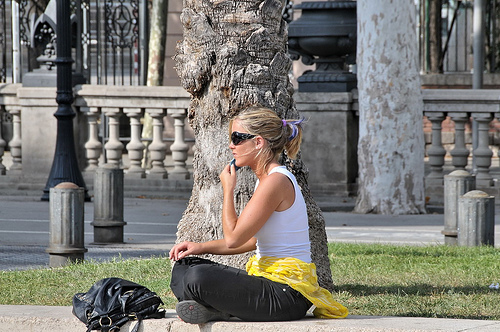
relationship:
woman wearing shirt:
[166, 105, 352, 323] [254, 165, 314, 266]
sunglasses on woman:
[231, 131, 257, 146] [166, 105, 352, 323]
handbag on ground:
[72, 277, 166, 330] [0, 241, 499, 331]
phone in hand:
[229, 158, 240, 173] [219, 162, 238, 193]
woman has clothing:
[166, 105, 352, 323] [244, 254, 350, 318]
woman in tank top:
[166, 105, 352, 323] [254, 165, 314, 266]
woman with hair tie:
[166, 105, 352, 323] [282, 115, 305, 140]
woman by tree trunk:
[166, 105, 352, 323] [173, 0, 335, 294]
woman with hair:
[166, 105, 352, 323] [229, 108, 304, 178]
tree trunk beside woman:
[173, 0, 335, 294] [166, 105, 352, 323]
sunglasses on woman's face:
[231, 131, 257, 146] [229, 121, 253, 168]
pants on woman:
[171, 256, 313, 321] [166, 105, 352, 323]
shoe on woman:
[176, 300, 233, 324] [166, 105, 352, 323]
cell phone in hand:
[229, 158, 240, 173] [219, 162, 238, 193]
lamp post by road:
[40, 0, 91, 201] [0, 199, 499, 268]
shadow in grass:
[333, 280, 499, 298] [1, 239, 499, 319]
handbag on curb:
[72, 277, 166, 330] [0, 303, 500, 331]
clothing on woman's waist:
[244, 254, 350, 318] [256, 255, 314, 275]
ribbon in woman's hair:
[282, 115, 305, 140] [229, 108, 304, 178]